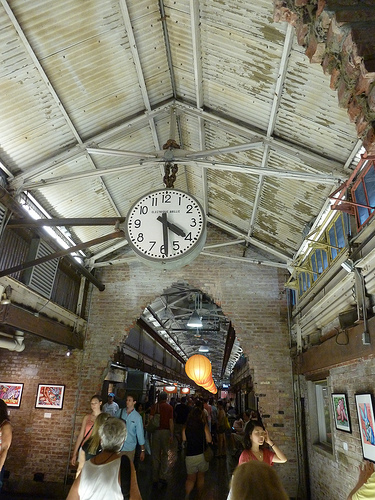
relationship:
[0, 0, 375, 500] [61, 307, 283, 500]
looks like an old train station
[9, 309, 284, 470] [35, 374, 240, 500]
looks like a long building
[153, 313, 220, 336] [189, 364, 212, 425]
fluorescent lights above orange ones